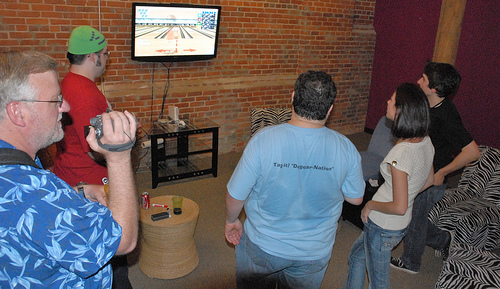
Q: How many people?
A: Five.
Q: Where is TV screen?
A: On wall.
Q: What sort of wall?
A: Brick.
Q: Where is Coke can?
A: On table.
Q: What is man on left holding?
A: Video camera.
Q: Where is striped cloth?
A: On couch.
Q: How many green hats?
A: One.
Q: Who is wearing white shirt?
A: Woman.